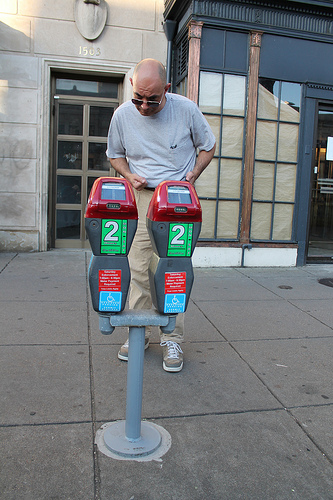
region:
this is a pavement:
[231, 280, 312, 410]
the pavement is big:
[186, 385, 305, 459]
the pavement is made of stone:
[181, 401, 312, 492]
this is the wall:
[3, 111, 33, 200]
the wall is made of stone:
[4, 109, 34, 223]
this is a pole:
[124, 382, 142, 441]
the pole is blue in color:
[123, 381, 144, 439]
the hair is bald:
[135, 59, 166, 85]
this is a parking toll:
[91, 174, 197, 311]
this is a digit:
[165, 221, 189, 251]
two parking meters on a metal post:
[90, 172, 188, 462]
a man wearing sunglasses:
[103, 60, 214, 181]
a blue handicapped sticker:
[94, 289, 123, 313]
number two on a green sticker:
[101, 220, 126, 253]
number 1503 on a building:
[0, 37, 164, 67]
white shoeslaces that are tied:
[161, 342, 186, 365]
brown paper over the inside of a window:
[192, 57, 304, 246]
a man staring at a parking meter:
[82, 62, 219, 222]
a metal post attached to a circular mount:
[82, 307, 173, 461]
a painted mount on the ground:
[88, 407, 180, 466]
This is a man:
[99, 40, 227, 421]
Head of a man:
[124, 46, 179, 124]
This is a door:
[45, 62, 145, 285]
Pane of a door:
[54, 96, 82, 136]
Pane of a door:
[55, 134, 86, 176]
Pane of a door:
[55, 170, 85, 209]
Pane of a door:
[55, 207, 82, 244]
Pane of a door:
[84, 99, 125, 140]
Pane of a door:
[88, 139, 119, 172]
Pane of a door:
[198, 66, 222, 114]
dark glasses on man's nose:
[128, 86, 172, 118]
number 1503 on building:
[69, 34, 117, 64]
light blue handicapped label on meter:
[160, 291, 198, 320]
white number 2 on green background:
[164, 222, 197, 256]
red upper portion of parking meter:
[143, 180, 214, 223]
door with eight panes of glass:
[56, 96, 116, 242]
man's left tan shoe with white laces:
[161, 336, 192, 373]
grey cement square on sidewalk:
[194, 295, 330, 356]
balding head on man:
[129, 59, 175, 92]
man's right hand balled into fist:
[123, 168, 150, 192]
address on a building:
[66, 43, 110, 63]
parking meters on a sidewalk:
[70, 162, 218, 333]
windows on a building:
[261, 71, 297, 239]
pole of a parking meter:
[103, 312, 169, 465]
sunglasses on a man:
[128, 88, 165, 111]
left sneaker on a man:
[157, 337, 187, 372]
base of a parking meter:
[95, 413, 176, 461]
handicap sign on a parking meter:
[158, 293, 187, 317]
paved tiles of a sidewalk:
[211, 314, 324, 490]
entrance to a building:
[35, 57, 112, 255]